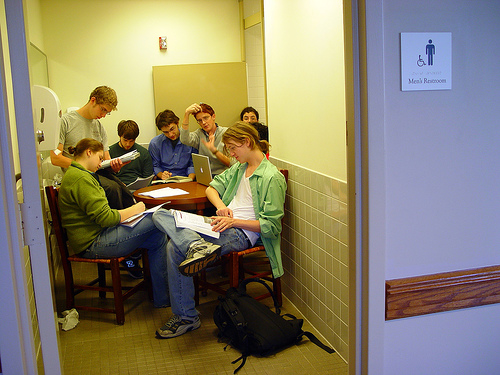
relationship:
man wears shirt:
[133, 90, 195, 186] [150, 133, 195, 176]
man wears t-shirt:
[49, 85, 134, 209] [55, 110, 107, 155]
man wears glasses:
[180, 104, 237, 177] [196, 115, 212, 125]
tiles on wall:
[239, 148, 406, 373] [256, 146, 358, 364]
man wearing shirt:
[150, 122, 286, 340] [204, 154, 285, 202]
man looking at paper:
[148, 110, 196, 187] [148, 170, 198, 187]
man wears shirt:
[153, 122, 287, 337] [206, 150, 288, 279]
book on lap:
[112, 189, 239, 245] [103, 174, 245, 269]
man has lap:
[144, 110, 307, 342] [103, 174, 245, 269]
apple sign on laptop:
[196, 164, 205, 177] [183, 150, 218, 189]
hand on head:
[201, 126, 220, 151] [65, 135, 108, 173]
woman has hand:
[176, 96, 240, 186] [201, 126, 220, 151]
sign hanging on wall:
[398, 28, 453, 93] [372, 13, 497, 368]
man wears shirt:
[144, 110, 307, 342] [193, 150, 317, 285]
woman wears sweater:
[57, 137, 167, 307] [58, 162, 113, 252]